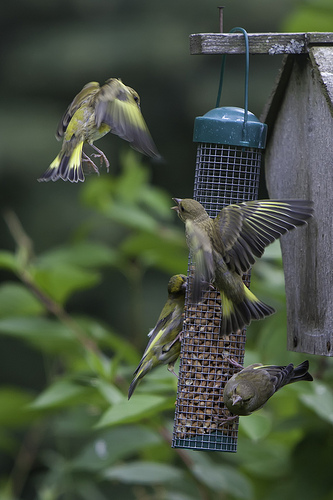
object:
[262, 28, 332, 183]
birdhouse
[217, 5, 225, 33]
nail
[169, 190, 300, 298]
bird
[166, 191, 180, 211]
mouth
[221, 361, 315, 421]
bird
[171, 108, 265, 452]
bird feeder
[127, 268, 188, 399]
bird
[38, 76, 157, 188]
bird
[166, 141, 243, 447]
wire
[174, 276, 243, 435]
seeds